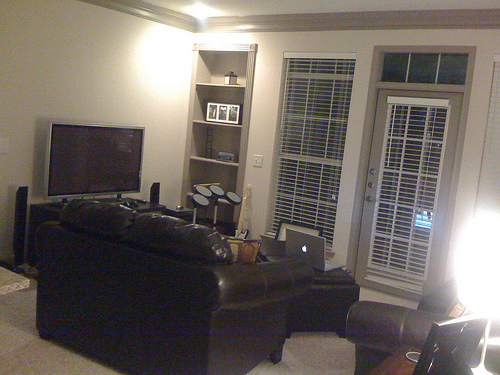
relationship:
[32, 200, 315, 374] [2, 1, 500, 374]
loveseat in room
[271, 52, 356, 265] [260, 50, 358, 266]
blinds on window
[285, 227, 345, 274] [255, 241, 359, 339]
laptop on ottoman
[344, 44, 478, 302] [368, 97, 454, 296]
door has blinds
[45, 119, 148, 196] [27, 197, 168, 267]
tv on stand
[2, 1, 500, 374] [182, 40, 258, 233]
room has shelves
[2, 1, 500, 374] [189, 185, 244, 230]
room has drums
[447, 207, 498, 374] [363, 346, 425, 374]
lamp on stand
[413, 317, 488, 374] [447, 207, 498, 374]
picture frame beside lamp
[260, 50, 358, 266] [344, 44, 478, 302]
window beside door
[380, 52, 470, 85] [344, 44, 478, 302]
windows over door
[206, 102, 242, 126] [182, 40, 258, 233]
picture frame on shelves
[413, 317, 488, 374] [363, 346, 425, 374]
picture frame on stand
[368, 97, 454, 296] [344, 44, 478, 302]
blinds on door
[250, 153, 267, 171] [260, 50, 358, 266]
light switch beside window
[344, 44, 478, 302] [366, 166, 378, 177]
door has lock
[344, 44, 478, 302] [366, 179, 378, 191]
door has lock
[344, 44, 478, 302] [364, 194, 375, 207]
door has lock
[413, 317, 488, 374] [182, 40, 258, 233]
picture frame on shelves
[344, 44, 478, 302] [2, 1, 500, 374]
door in room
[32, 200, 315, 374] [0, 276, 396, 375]
loveseat on floor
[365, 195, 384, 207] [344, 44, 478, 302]
handle on door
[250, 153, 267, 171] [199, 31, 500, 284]
light switch on wall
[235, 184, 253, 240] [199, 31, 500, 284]
guitar against wall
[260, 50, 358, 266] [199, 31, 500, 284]
window on wall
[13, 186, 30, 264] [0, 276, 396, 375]
speaker on floor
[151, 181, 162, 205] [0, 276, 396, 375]
speaker on floor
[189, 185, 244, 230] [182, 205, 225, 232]
drums on stand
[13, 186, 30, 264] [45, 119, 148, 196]
speaker beside tv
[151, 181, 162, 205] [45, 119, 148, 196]
speaker beside tv